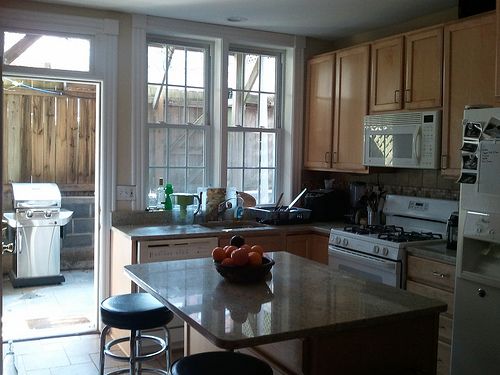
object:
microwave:
[362, 108, 442, 171]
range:
[325, 192, 460, 291]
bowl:
[213, 258, 271, 283]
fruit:
[212, 234, 264, 265]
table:
[120, 247, 449, 375]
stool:
[97, 291, 172, 374]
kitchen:
[2, 0, 499, 374]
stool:
[172, 347, 274, 375]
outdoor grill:
[3, 182, 75, 289]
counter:
[107, 217, 351, 359]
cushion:
[98, 289, 174, 329]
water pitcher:
[169, 192, 202, 229]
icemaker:
[448, 103, 499, 374]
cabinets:
[300, 14, 499, 179]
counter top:
[108, 207, 348, 241]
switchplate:
[116, 184, 137, 201]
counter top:
[124, 248, 448, 351]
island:
[181, 313, 446, 374]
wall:
[24, 113, 79, 171]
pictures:
[460, 115, 499, 186]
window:
[140, 26, 294, 214]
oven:
[328, 193, 458, 289]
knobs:
[381, 247, 389, 256]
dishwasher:
[133, 234, 224, 355]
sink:
[195, 214, 273, 233]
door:
[2, 76, 99, 344]